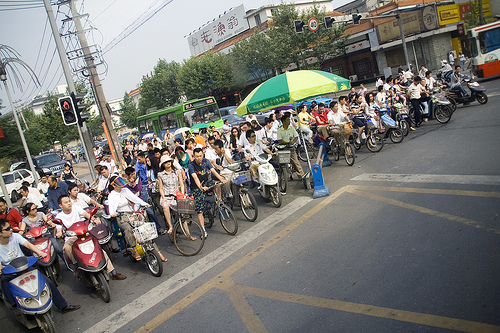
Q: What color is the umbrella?
A: Green and yellow.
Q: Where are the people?
A: On the street.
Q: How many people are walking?
A: None.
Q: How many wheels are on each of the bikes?
A: Two.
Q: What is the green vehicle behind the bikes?
A: A bus.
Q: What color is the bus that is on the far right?
A: Red and white.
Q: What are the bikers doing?
A: Lining up.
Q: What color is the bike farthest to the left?
A: Blue.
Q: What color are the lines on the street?
A: White and yellow.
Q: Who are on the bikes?
A: People.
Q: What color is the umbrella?
A: Green and yellow.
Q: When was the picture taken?
A: Daytime.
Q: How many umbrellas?
A: 1.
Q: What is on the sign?
A: Do not cross.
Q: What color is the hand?
A: Red.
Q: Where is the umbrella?
A: Middle of the road.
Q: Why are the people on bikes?
A: For a race.